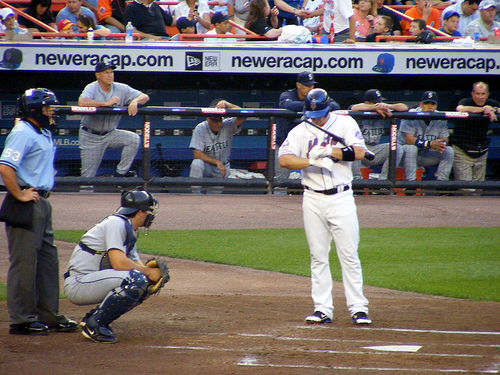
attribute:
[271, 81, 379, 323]
baseball batter — Standing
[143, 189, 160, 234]
mask — Black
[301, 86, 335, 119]
helmet — blue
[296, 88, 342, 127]
helmet — blue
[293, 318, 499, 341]
line — long, white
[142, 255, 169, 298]
mit — Brown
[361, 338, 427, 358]
base — white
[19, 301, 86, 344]
man's shoe — black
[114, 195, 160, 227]
helmet — blue, on catcher's head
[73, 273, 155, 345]
guards — Black 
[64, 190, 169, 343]
catcher — professional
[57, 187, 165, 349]
catcher — crouching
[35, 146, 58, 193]
shirt — blue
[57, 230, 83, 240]
grass — green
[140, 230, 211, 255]
grass — green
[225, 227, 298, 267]
grass — green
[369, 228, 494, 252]
grass — green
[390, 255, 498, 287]
grass — green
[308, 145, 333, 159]
glove — white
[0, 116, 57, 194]
blue jersey — light blue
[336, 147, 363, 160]
arm band — black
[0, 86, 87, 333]
umpire — Squatting 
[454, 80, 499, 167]
baseball coach — professional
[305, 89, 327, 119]
hard helmet — blue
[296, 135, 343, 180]
batting gloves — baseball player's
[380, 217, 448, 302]
grass — big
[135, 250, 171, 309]
glove — white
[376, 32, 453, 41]
pole — long, orange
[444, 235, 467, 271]
tree — white